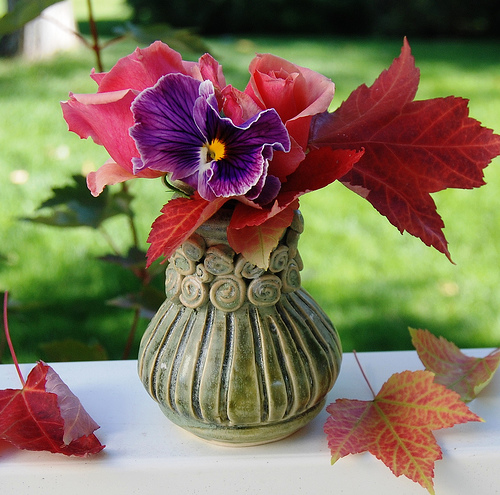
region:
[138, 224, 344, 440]
green ceramic vase on table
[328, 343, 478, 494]
red and yellow leaf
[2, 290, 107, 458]
red leaf on table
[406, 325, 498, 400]
leaf sitting on table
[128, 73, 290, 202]
purple flower in vase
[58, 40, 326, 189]
pink flowers in vase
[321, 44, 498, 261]
red leaf in vase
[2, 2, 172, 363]
plant with green leaves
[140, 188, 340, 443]
green vase on table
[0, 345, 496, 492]
white table in yard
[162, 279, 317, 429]
a small vase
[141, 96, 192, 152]
purple flower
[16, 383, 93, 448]
a red leaf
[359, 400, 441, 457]
a leaf on the table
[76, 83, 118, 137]
a red flower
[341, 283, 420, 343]
a shadow on the grass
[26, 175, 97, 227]
the leaves are green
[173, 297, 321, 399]
the vase is green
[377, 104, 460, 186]
the red leaves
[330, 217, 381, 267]
the grass is green in the field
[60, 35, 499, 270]
the flowers and leaves in the vase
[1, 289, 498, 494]
the leaves next to the vase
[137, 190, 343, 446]
the vase holding the flowers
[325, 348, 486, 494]
the leafe next to the vase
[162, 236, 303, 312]
the swirls on the vase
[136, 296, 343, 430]
the grooves on the vase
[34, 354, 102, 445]
the curled piece on the leaf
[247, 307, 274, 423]
the groove on the vase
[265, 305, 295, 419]
the groove on the vase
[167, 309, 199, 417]
the groove on the vase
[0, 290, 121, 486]
loose red leaf on table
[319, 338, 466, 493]
loose red and green leaf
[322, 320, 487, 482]
two loose green and red leaves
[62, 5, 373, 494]
green vase with flowers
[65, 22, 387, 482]
flowers in vase on table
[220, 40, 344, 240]
pink rose in vase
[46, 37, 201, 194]
pink rose in vase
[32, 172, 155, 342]
green leaves in back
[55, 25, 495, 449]
Colorful flowers and leaves in a vase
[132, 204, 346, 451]
A decorative green vase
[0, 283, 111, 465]
A red leaf on a table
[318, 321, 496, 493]
Two fall leaves on a table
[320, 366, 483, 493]
The veins of a leaf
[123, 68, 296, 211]
A purple flower with a yellow center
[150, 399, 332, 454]
The base of a vase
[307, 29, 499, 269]
A large red leaf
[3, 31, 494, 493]
A flower vase and leaves on a white surface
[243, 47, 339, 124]
The top of a rose